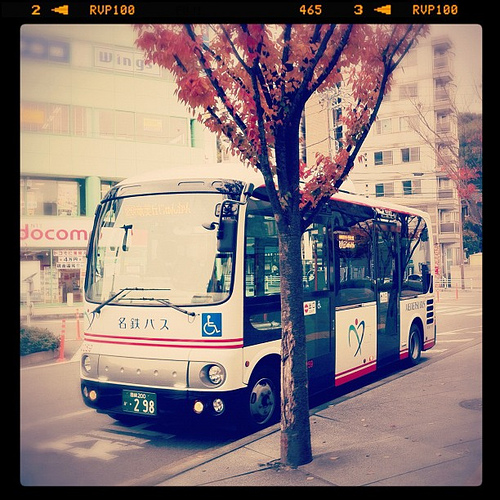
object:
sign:
[201, 312, 222, 337]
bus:
[79, 168, 436, 430]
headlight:
[209, 366, 223, 384]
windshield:
[85, 193, 238, 306]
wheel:
[409, 324, 423, 365]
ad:
[334, 301, 377, 387]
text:
[119, 317, 169, 330]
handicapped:
[203, 314, 220, 335]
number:
[134, 398, 140, 411]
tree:
[133, 21, 430, 463]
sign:
[21, 224, 88, 241]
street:
[21, 425, 95, 485]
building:
[304, 24, 466, 286]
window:
[397, 112, 420, 134]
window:
[399, 213, 430, 296]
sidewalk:
[384, 400, 484, 487]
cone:
[58, 319, 66, 360]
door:
[377, 222, 400, 370]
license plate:
[122, 389, 157, 416]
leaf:
[361, 40, 373, 58]